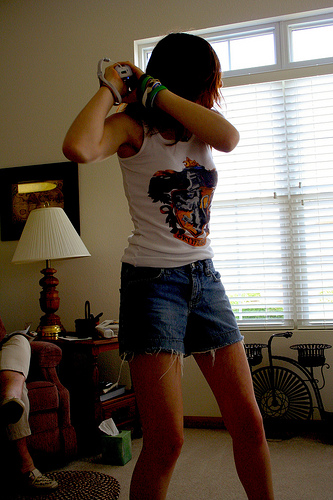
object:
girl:
[60, 27, 275, 500]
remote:
[114, 63, 134, 84]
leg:
[128, 311, 188, 499]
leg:
[185, 298, 274, 499]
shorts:
[113, 260, 245, 358]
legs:
[1, 328, 33, 434]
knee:
[162, 419, 190, 459]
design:
[146, 156, 218, 248]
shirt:
[118, 108, 220, 269]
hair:
[145, 29, 226, 118]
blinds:
[241, 77, 333, 323]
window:
[211, 19, 332, 332]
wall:
[0, 0, 80, 108]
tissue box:
[96, 415, 133, 468]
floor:
[0, 426, 332, 500]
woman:
[1, 307, 61, 500]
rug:
[26, 467, 118, 499]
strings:
[115, 353, 185, 391]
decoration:
[243, 332, 332, 439]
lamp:
[10, 201, 93, 342]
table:
[60, 327, 136, 440]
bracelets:
[134, 71, 170, 111]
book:
[100, 381, 131, 403]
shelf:
[95, 382, 143, 418]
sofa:
[25, 339, 78, 463]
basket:
[74, 300, 100, 337]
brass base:
[33, 316, 68, 341]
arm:
[133, 63, 242, 156]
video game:
[95, 53, 136, 105]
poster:
[1, 169, 65, 204]